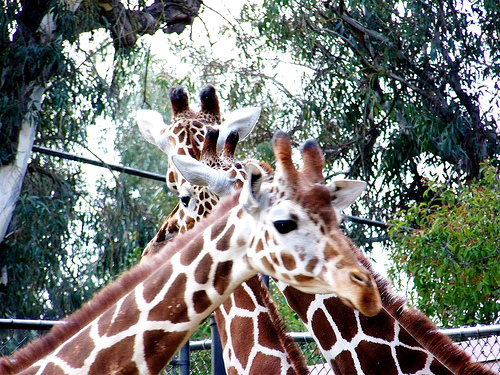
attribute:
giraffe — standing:
[0, 129, 383, 374]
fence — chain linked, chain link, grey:
[0, 317, 499, 374]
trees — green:
[0, 0, 497, 375]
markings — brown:
[0, 129, 384, 374]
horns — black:
[272, 130, 324, 188]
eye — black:
[272, 220, 298, 234]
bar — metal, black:
[31, 144, 417, 233]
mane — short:
[1, 190, 243, 373]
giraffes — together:
[1, 85, 499, 373]